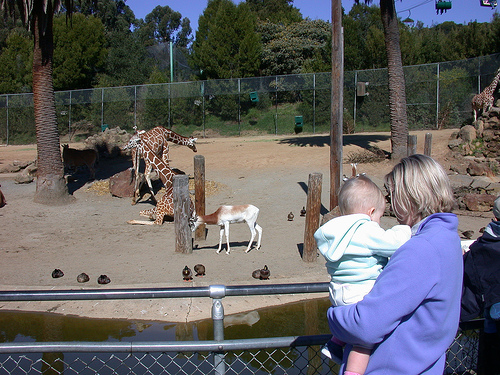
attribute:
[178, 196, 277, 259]
goat — white, brown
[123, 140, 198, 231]
giraffe — brown, beige, sitting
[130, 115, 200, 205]
giraffe — standing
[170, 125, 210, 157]
head — low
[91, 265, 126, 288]
duck — sitting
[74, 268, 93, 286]
duck — sitting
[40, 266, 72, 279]
duck — sitting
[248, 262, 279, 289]
duck — sitting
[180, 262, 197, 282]
duck — standing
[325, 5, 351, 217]
pole — wooden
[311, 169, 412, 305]
baby — girl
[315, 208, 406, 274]
hoodie — white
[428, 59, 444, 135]
pole — long, grey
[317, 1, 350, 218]
post — wooden, tall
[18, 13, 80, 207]
tree trunk — tall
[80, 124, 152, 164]
rock — gray, big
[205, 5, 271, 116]
tree — green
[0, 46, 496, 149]
fence — metal, linked, gray, chain link, tall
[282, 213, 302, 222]
bird — small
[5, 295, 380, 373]
water — murky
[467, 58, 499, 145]
giraffe — alone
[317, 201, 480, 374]
jacket — blue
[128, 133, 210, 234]
animal — brown, white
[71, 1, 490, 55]
sky — clear, deep blue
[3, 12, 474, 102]
trees — lush, green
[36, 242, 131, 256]
dirt — gray, brown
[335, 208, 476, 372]
sweater — lavender, hooded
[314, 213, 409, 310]
sweater — white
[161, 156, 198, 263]
tree trunk — brown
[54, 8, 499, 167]
trees — green